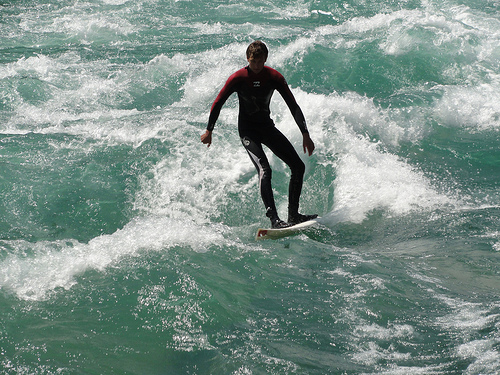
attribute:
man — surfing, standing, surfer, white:
[202, 33, 325, 222]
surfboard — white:
[256, 215, 335, 238]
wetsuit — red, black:
[245, 70, 299, 213]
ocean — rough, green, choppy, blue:
[18, 237, 481, 357]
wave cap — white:
[347, 166, 437, 213]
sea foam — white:
[67, 235, 143, 267]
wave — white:
[307, 27, 462, 78]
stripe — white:
[250, 153, 268, 189]